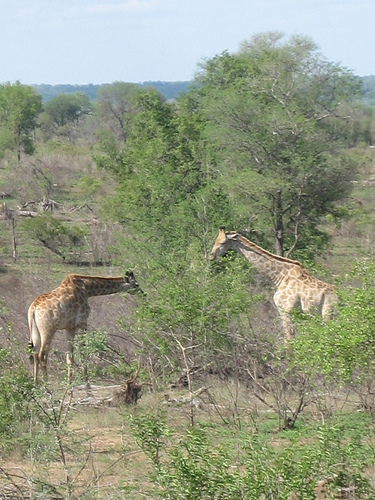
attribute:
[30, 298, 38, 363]
tail — swinging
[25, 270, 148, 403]
giraffe — spotted, eating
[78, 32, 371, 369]
tree — green, tall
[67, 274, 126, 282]
hair — brown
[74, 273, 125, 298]
neck — long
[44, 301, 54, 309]
spot — brown, white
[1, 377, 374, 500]
grass — dry, brown